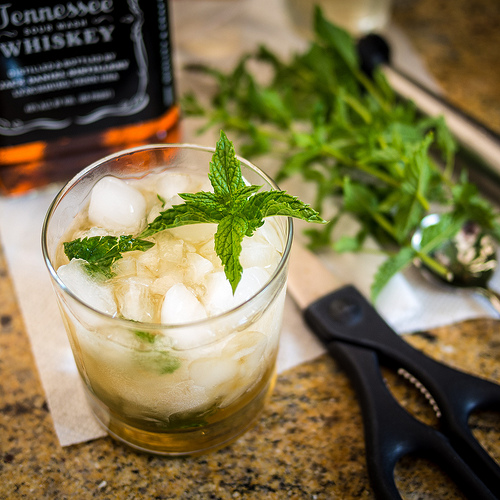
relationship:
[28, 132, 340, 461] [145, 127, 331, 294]
glass with a leaf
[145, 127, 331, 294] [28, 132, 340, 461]
leaf inside glass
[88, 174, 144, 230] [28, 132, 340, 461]
ice cube inside glass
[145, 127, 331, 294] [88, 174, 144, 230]
leaf near ice cube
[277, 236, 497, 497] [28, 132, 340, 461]
scissors near a glass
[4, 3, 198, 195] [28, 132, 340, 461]
bottle across from glass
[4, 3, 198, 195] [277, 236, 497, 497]
bottle across from scissors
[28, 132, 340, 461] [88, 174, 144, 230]
glass with a ice cube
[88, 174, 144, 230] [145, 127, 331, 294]
ice cube near leaf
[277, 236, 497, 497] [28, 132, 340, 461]
scissors next to glass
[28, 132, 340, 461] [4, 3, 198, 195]
glass near bottle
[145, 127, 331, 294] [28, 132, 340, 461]
leaf inside a glass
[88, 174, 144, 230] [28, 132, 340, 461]
ice cube inside a glass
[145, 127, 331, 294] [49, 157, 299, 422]
leaf in drink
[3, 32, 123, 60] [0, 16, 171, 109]
"whiskey" printed on label